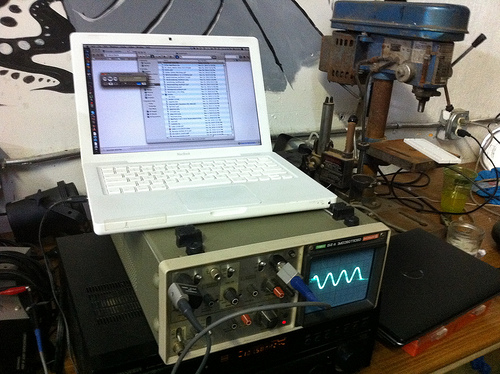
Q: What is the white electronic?
A: Laptop computer.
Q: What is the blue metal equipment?
A: Drill press.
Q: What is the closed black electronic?
A: Laptop computer.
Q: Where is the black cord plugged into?
A: White laptop computer.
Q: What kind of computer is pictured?
A: A laptop.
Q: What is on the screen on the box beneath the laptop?
A: A wave.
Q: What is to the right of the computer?
A: A drill.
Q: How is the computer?
A: Turned on.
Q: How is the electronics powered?
A: Electricity.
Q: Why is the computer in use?
A: To search for information.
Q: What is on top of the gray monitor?
A: White laptop.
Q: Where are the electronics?
A: Top of a table.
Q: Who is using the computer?
A: An employee.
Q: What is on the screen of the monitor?
A: Wave signals.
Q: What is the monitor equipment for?
A: Testing.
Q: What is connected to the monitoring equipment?
A: Plugs to other equipment.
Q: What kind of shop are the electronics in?
A: Repair.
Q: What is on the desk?
A: A meter.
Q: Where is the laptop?
A: On top of meter.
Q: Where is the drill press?
A: To the right of the laptop.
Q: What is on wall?
A: A mural.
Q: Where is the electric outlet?
A: By the drill press on the right.